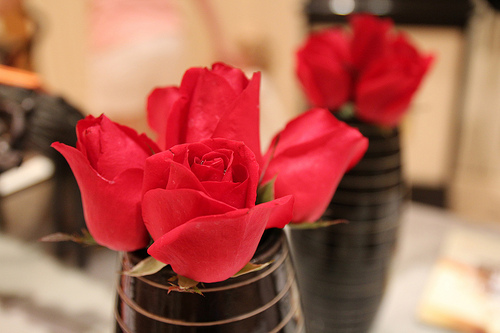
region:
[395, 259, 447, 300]
shiny silver covering on the table top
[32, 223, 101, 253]
green stem on flowers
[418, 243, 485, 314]
yellow and white object on table top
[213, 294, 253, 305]
shiny black vase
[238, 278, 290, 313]
lines around the black vase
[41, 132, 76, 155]
tiny edge of red rose petal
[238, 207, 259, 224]
tiny black spot on rose petal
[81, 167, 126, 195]
small groove in the rose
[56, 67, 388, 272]
bouquet of red roses in vase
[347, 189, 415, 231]
base of black vase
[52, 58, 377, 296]
four red rose buds in a vase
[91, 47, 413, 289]
two vases with red roses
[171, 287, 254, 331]
a brown vase with gold trim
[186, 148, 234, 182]
the heart of a red rose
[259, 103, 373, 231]
a red rose bud blooming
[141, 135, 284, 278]
a red rose bud blooming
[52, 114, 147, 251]
a red rose bud blooming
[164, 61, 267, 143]
a red rose bud blooming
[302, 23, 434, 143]
a bunch of a red roses in a vase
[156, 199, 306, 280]
a petal of a red rose bud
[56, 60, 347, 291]
4 flowers bunched together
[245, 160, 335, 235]
green leaves on the flower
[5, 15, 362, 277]
the flowers are roses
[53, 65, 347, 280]
the roses are red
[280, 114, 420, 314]
black vase holding flowers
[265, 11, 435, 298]
the flowers on the right are blurry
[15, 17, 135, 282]
the background is blurry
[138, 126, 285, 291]
the flower is opening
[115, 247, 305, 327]
the vase has lines on it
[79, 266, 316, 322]
the lines are white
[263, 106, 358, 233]
Unopened red colored rosebud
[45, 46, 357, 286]
Four slightly opened rosebuds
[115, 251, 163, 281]
Leaf on a rosebud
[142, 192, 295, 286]
Red rose petal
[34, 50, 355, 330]
Roses in a brown vase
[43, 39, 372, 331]
Red roses in a brown vase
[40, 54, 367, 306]
Small bouquet of red roses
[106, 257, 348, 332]
Chocolate brown vase with light coffee colored lines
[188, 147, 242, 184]
View looking into the top center of a rosebud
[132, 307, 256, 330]
Thin, light brown line on a vase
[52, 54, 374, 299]
THESE ARE ROSES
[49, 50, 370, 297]
THE ROSES ARE RED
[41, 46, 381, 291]
THE ROSES ARE NOT FULLY OPENED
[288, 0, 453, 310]
THIS IS A REFLECTION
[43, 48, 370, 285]
THE ROSES ARE IN A VASE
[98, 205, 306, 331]
THE VASE IS BLACK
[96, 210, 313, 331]
THE VASE IS SHINY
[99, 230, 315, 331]
THE VASE HAS GOLD STRIPES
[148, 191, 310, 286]
THIS IS A ROSE PETAL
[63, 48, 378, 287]
THE FOUR ROSES ARE SHORT STEMMED